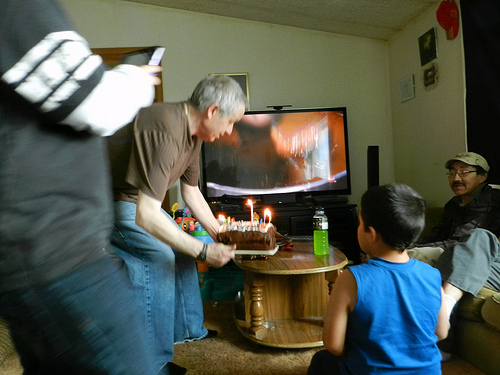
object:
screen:
[200, 106, 352, 198]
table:
[230, 240, 349, 350]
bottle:
[314, 207, 330, 255]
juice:
[312, 231, 331, 255]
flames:
[248, 199, 253, 206]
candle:
[251, 206, 254, 226]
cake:
[218, 221, 276, 250]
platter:
[232, 245, 280, 255]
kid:
[307, 181, 449, 374]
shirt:
[341, 260, 442, 374]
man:
[438, 151, 500, 316]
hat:
[444, 151, 492, 173]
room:
[1, 0, 500, 372]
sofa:
[415, 206, 499, 374]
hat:
[434, 0, 461, 42]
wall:
[67, 0, 470, 205]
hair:
[189, 73, 248, 116]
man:
[111, 73, 234, 340]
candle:
[264, 210, 266, 226]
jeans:
[109, 199, 208, 367]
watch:
[195, 242, 207, 263]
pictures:
[397, 25, 442, 104]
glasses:
[446, 169, 478, 176]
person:
[0, 2, 167, 374]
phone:
[119, 45, 164, 68]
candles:
[224, 221, 226, 227]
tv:
[196, 107, 352, 211]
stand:
[249, 194, 309, 208]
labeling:
[310, 218, 330, 231]